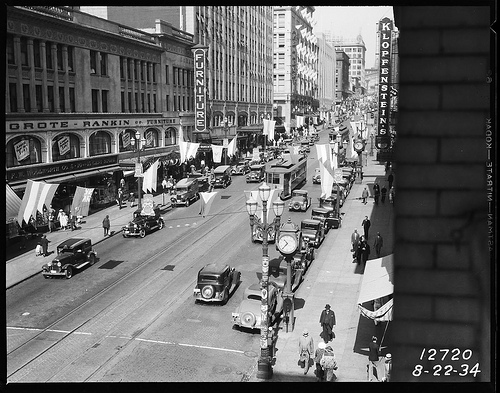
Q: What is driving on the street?
A: Cars.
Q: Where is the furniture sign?
A: On the building.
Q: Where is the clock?
A: On a pole.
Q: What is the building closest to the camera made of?
A: Brick.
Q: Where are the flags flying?
A: Along the street.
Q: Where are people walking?
A: On the sidewalks.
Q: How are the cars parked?
A: Parallel to the sidewalk.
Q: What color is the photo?
A: Black and white.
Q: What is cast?
A: Shadow.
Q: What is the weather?
A: Sunny.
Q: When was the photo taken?
A: Daytime.